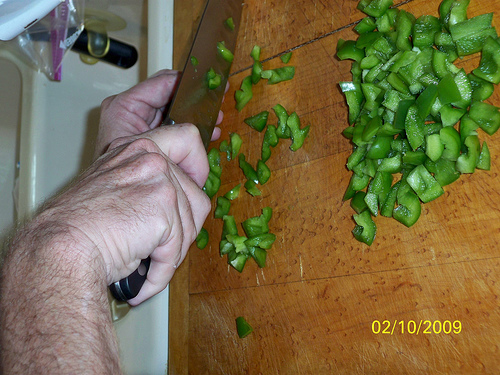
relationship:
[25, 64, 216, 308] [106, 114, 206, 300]
hand holding handle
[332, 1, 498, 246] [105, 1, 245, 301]
green pepper reflected on knife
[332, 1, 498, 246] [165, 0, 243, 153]
green pepper reflected on blade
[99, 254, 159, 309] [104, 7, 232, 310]
handle on knife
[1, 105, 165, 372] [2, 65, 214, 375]
forearms on male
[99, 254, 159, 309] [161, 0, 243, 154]
handle belonging to knife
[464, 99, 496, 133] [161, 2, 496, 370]
pepper lying on cutting board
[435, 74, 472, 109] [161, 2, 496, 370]
pepper lying on cutting board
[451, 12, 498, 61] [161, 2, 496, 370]
pepper lying on cutting board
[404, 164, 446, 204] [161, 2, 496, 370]
pepper lying on cutting board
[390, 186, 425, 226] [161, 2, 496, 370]
pepper lying on cutting board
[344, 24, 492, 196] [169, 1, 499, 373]
peppers on table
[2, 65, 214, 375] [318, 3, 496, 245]
male cutting peppers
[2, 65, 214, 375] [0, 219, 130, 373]
male has arm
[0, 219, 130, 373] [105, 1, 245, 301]
arm holding knife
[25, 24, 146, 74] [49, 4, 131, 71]
object in holder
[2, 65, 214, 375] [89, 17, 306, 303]
male holding knife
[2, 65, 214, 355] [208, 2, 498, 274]
male cutting peppers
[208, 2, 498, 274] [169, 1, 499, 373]
peppers on table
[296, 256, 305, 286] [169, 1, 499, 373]
scratches on table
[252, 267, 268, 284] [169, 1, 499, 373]
scratches on table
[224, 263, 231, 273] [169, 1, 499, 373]
scratches on table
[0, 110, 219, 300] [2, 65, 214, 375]
hand of male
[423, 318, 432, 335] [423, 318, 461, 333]
2 in 2009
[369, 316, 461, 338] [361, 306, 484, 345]
date in print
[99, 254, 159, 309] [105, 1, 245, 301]
handle of knife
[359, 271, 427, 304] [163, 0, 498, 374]
marks of board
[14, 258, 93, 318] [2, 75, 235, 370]
hair of arm